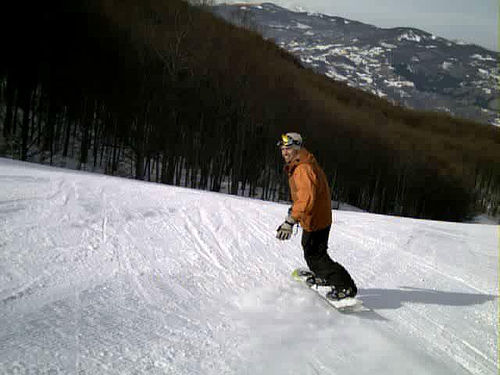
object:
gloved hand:
[275, 220, 294, 241]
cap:
[276, 131, 303, 149]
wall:
[433, 58, 475, 113]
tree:
[165, 55, 189, 186]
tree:
[265, 62, 286, 202]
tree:
[95, 34, 122, 176]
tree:
[36, 13, 61, 162]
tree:
[0, 1, 28, 159]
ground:
[0, 155, 500, 374]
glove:
[275, 216, 297, 241]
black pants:
[301, 223, 356, 292]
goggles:
[276, 138, 301, 147]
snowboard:
[291, 268, 365, 316]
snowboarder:
[269, 122, 359, 306]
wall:
[192, 0, 301, 31]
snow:
[0, 105, 500, 375]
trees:
[376, 129, 412, 216]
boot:
[325, 281, 357, 302]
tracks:
[0, 157, 500, 374]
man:
[274, 132, 356, 302]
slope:
[0, 212, 500, 375]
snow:
[274, 21, 420, 98]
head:
[276, 131, 303, 164]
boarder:
[275, 131, 357, 301]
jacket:
[283, 146, 333, 233]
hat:
[276, 132, 302, 151]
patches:
[0, 156, 465, 375]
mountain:
[0, 0, 500, 226]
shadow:
[351, 285, 499, 321]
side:
[2, 1, 500, 221]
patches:
[212, 4, 444, 118]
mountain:
[204, 0, 500, 125]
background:
[0, 1, 499, 374]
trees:
[131, 0, 161, 181]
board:
[290, 266, 365, 314]